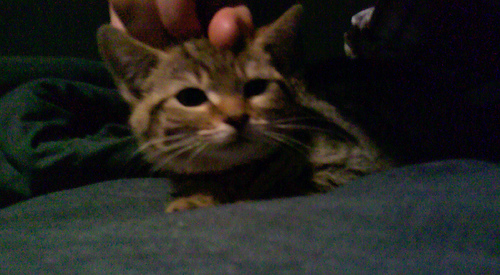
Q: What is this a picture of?
A: A cat.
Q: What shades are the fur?
A: Black and white and brown.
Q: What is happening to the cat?
A: It is getting petted.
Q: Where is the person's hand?
A: On cat's head.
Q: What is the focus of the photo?
A: Animal.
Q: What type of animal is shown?
A: Cat.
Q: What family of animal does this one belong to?
A: Feline.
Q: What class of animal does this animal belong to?
A: Mammal.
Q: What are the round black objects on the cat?
A: Eyes.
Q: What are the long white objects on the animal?
A: Whiskers.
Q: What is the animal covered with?
A: Fur.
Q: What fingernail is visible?
A: Thumb.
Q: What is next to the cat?
A: A blanket.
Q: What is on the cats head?
A: A person's hand.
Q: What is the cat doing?
A: Sitting on the ground.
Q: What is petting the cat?
A: A person.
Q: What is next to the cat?
A: Green fabric.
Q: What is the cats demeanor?
A: Relaxed.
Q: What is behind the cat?
A: A person.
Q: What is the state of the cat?
A: Relaxed.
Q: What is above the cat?
A: A hand.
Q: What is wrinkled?
A: Pillow.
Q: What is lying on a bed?
A: Cat.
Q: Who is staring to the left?
A: Cat.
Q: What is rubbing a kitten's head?
A: A hand.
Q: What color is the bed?
A: Blue.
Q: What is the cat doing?
A: Laying down.